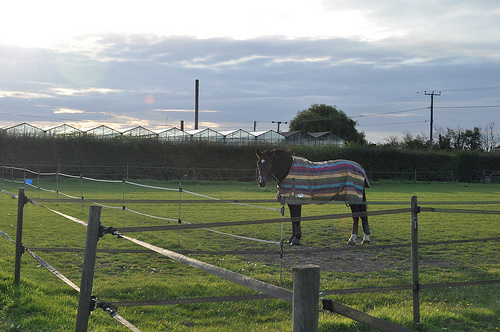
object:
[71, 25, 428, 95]
clouds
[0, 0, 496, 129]
sky